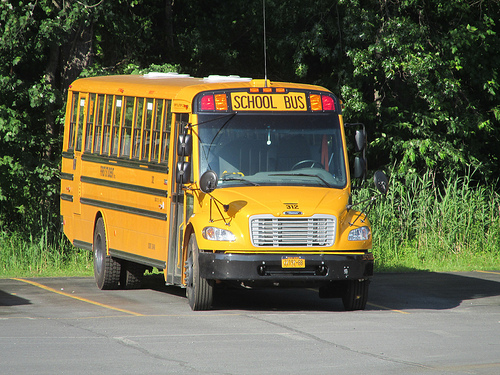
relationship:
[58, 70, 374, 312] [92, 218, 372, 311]
bus has tires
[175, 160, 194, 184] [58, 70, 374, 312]
mirror on bus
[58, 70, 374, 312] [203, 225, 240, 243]
bus has right headlight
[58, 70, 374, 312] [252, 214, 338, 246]
bus has grill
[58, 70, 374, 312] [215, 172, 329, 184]
bus has front windshield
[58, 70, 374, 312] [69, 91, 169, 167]
bus has windows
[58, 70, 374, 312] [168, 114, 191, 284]
bus has door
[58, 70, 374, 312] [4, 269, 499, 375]
bus on parking lot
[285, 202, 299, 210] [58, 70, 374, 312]
312 on bus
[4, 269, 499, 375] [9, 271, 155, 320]
parking lot has line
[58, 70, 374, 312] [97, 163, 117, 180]
bus has writing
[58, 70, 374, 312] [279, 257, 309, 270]
bus has license plate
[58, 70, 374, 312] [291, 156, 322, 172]
bus has steering wheel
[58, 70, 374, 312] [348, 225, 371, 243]
bus has left headlight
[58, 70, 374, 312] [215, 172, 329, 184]
bus has windshield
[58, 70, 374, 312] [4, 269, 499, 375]
bus in parking lot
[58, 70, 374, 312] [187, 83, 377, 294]
bus has head